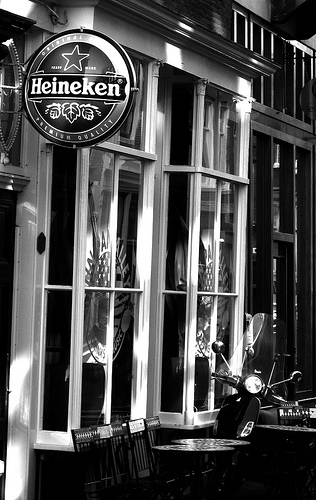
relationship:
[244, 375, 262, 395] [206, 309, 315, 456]
headlight on bike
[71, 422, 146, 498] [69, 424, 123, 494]
seat has back rest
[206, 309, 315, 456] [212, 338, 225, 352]
bike has mirror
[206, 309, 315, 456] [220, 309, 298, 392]
bike has windshield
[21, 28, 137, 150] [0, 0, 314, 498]
sign in front of restaurant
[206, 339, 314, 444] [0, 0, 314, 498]
bike in front of restaurant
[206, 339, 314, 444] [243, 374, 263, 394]
bike has headlight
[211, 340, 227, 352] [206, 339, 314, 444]
mirror on bike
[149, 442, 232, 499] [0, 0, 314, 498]
table in front of restaurant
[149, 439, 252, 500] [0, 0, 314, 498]
table in front of restaurant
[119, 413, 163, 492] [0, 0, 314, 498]
chair in front of restaurant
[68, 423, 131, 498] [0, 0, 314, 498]
chair in front of restaurant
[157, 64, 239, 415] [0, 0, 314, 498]
window in front of restaurant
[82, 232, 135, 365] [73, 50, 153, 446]
logo in front of window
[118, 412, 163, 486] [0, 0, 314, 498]
chair back in front of restaurant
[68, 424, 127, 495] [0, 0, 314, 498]
chair back in front of restaurant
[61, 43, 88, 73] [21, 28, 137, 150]
star on sign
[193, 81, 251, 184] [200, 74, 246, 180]
trim on window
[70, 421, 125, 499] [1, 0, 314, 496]
chair outside building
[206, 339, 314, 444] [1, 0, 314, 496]
bike leaning against building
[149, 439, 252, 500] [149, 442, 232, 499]
table next to table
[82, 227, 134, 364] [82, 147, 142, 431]
logo in pane